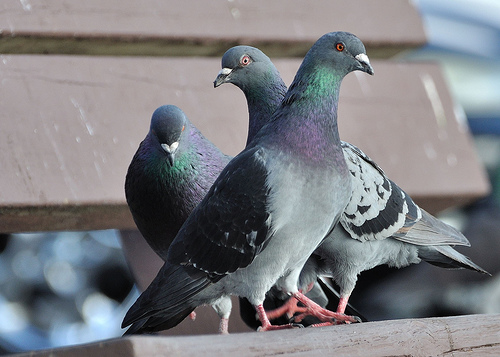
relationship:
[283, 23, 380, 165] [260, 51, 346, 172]
pigeon has neck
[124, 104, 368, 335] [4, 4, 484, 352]
pigeon standing on bench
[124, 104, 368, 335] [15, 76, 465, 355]
pigeon on bench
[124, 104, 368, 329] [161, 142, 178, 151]
pigeon has white beak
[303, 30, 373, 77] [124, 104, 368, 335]
head of a pigeon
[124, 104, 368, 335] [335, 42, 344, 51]
pigeon with eye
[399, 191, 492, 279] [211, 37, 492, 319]
tail feathers of a pigeon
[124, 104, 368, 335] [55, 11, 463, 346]
pigeon droppings on back of bench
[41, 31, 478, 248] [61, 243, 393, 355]
boards on bench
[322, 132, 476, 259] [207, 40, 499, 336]
wing of a pigeon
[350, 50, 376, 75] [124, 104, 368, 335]
beak of a pigeon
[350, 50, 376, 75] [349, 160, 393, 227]
beak of a markings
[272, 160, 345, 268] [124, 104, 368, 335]
abdomens of pigeon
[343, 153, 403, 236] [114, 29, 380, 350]
feathers on side of bird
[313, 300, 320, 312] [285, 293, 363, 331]
part of a claw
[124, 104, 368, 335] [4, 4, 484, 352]
pigeon on a bench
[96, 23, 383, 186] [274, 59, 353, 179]
heads with multicolored feathers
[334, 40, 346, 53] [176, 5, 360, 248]
eye of pigeons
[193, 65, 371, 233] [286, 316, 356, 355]
pigeon on bench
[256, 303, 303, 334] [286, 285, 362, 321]
feet of feet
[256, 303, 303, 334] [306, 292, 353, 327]
feet of feet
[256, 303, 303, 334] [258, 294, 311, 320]
feet of feet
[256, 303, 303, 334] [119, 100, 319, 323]
feet of pigeons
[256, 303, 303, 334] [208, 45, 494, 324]
feet of pigeons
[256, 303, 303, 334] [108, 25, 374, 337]
feet of pigeons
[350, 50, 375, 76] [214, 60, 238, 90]
beak with beak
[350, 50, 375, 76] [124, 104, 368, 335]
beak with pigeon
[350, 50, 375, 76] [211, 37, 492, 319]
beak with pigeon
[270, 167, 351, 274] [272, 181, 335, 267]
feathers on abdomens